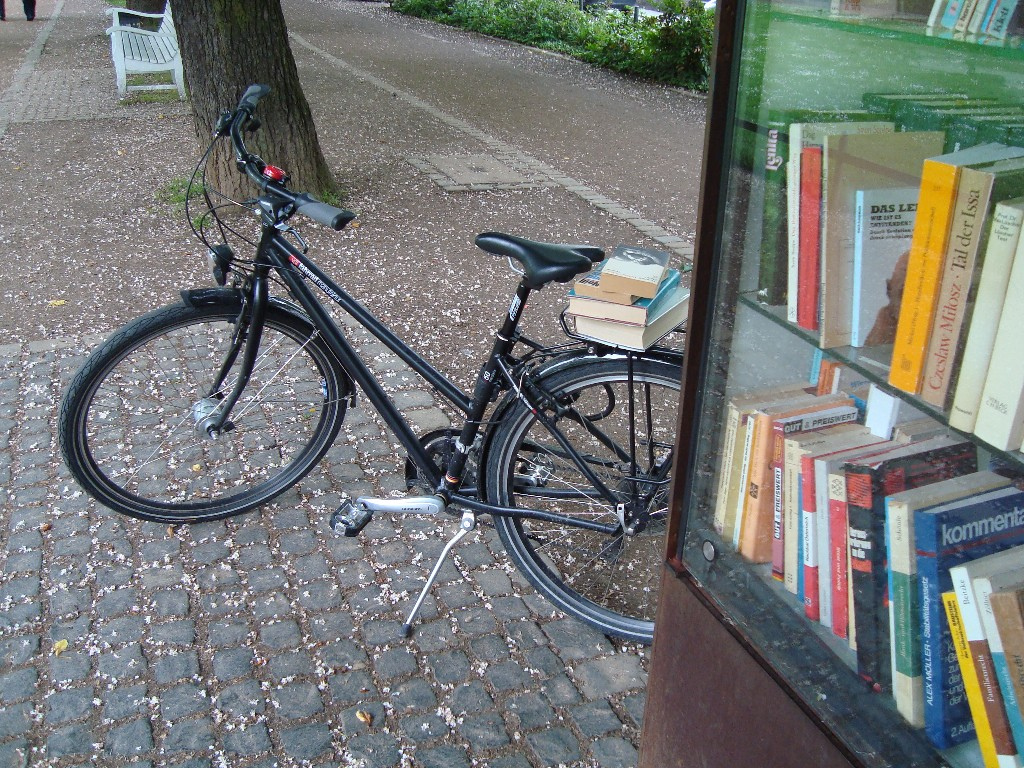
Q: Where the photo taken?
A: On the street.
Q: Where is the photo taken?
A: On the street.